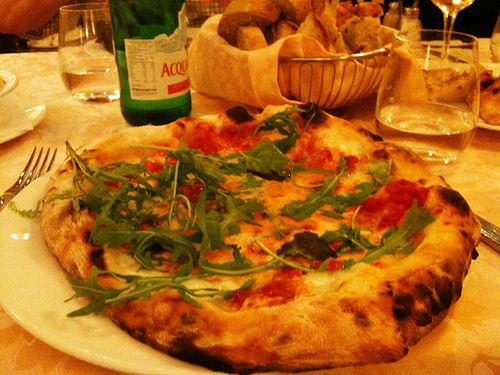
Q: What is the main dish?
A: Pizza.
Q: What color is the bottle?
A: Green.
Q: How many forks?
A: One.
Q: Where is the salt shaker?
A: Upper right quadrant.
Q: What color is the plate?
A: White.